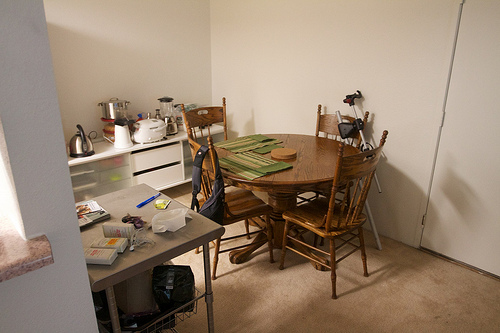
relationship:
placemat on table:
[215, 130, 281, 157] [203, 127, 366, 262]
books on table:
[217, 151, 292, 182] [203, 127, 366, 262]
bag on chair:
[191, 144, 226, 227] [177, 123, 279, 280]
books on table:
[223, 124, 344, 204] [202, 66, 422, 279]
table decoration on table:
[270, 147, 298, 159] [198, 130, 365, 270]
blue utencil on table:
[136, 189, 161, 209] [73, 178, 233, 331]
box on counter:
[114, 124, 134, 150] [65, 112, 226, 169]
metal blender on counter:
[156, 90, 177, 138] [68, 131, 189, 164]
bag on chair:
[181, 141, 228, 216] [184, 126, 285, 280]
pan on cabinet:
[93, 97, 136, 124] [69, 126, 196, 201]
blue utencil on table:
[136, 193, 161, 208] [203, 127, 366, 262]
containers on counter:
[84, 218, 139, 263] [76, 183, 224, 333]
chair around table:
[296, 103, 369, 246] [203, 127, 366, 262]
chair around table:
[278, 130, 388, 297] [203, 127, 366, 262]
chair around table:
[181, 121, 270, 279] [203, 127, 366, 262]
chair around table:
[179, 96, 251, 239] [203, 127, 366, 262]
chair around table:
[179, 96, 228, 143] [198, 130, 365, 270]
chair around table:
[278, 130, 389, 299] [198, 130, 365, 270]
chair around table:
[185, 129, 276, 282] [198, 130, 365, 270]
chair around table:
[296, 103, 369, 206] [198, 130, 365, 270]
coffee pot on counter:
[69, 124, 97, 159] [65, 120, 223, 167]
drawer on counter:
[130, 141, 182, 167] [118, 135, 187, 151]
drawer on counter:
[126, 163, 185, 188] [118, 135, 187, 151]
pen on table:
[133, 187, 160, 212] [76, 183, 226, 285]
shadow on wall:
[296, 96, 425, 246] [367, 27, 433, 82]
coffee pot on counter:
[68, 124, 94, 154] [56, 119, 226, 164]